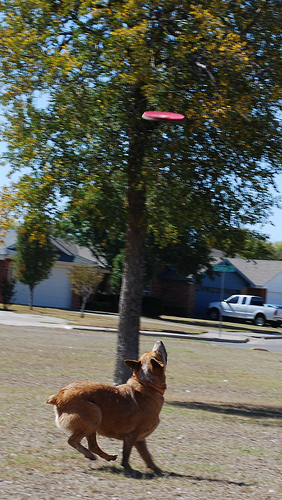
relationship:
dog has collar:
[46, 339, 168, 477] [130, 372, 166, 396]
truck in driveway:
[203, 293, 281, 327] [206, 314, 281, 335]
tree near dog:
[2, 2, 281, 388] [46, 339, 168, 477]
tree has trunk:
[2, 2, 281, 388] [112, 192, 148, 389]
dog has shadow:
[46, 339, 168, 477] [88, 465, 258, 487]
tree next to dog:
[2, 2, 281, 388] [46, 339, 168, 477]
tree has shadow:
[2, 2, 281, 388] [162, 395, 281, 427]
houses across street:
[1, 229, 281, 319] [0, 318, 282, 352]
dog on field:
[46, 339, 168, 477] [2, 324, 279, 499]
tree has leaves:
[2, 2, 281, 388] [0, 0, 281, 264]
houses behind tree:
[1, 229, 281, 319] [2, 2, 281, 388]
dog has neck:
[46, 339, 168, 477] [128, 369, 166, 401]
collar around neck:
[130, 372, 166, 396] [128, 369, 166, 401]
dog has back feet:
[46, 339, 168, 477] [80, 449, 119, 462]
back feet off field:
[80, 449, 119, 462] [2, 324, 279, 499]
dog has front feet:
[46, 339, 168, 477] [122, 464, 171, 476]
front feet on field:
[122, 464, 171, 476] [2, 324, 279, 499]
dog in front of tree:
[46, 339, 168, 477] [2, 2, 281, 388]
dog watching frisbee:
[46, 339, 168, 477] [139, 109, 188, 125]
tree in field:
[2, 2, 281, 388] [2, 324, 279, 499]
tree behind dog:
[2, 2, 281, 388] [46, 339, 168, 477]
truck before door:
[203, 293, 281, 327] [194, 290, 240, 323]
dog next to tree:
[46, 339, 168, 477] [2, 2, 281, 388]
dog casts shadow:
[46, 339, 168, 477] [88, 465, 258, 487]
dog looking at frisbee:
[46, 339, 168, 477] [139, 109, 188, 125]